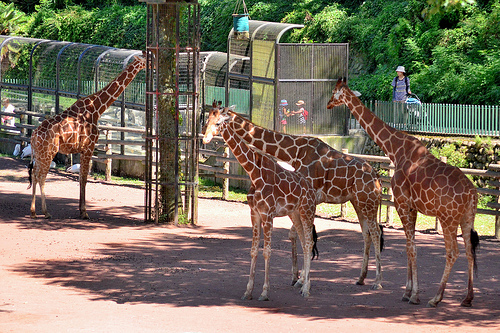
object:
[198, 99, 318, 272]
giraffes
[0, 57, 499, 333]
zoo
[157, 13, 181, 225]
tree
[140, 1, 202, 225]
cage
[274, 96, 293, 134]
children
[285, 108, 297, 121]
treats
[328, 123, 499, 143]
perimeter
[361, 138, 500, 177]
wall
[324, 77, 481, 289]
giraffe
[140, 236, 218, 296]
shadow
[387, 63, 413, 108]
person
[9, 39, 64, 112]
pen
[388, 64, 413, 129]
people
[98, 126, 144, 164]
fence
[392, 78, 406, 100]
shirt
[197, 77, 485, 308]
three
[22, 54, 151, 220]
alone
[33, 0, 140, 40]
trees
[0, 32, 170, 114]
enclosure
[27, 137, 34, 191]
tail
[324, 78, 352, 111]
head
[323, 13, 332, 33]
leaves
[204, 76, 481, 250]
together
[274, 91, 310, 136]
two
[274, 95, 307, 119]
playing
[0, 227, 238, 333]
ground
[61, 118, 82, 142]
sunlight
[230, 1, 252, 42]
object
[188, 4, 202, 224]
pole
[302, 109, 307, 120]
pack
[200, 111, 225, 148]
face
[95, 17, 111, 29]
green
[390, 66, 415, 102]
woman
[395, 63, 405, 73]
hat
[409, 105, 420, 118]
child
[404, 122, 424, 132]
stroller